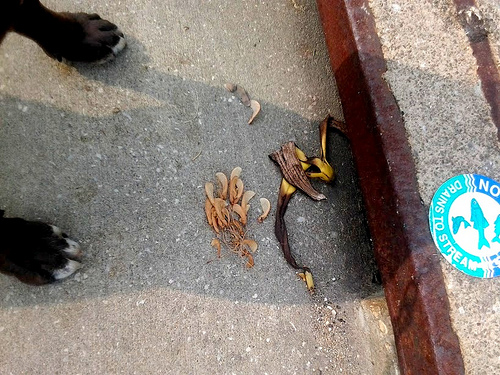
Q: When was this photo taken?
A: During the day.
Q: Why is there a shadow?
A: The dog is casting shade.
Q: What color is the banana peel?
A: Black.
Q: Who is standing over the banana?
A: A dog.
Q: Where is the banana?
A: In front of the dog.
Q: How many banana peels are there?
A: 1.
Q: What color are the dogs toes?
A: White.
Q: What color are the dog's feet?
A: Brown.